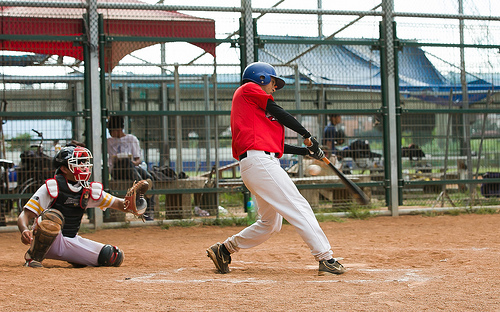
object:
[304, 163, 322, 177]
ball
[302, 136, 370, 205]
bat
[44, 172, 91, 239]
chestguard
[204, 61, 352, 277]
baseball player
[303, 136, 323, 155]
gloves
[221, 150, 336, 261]
white pants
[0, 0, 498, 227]
dugout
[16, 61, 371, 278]
game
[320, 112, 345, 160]
man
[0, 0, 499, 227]
fence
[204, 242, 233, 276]
shoe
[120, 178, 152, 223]
glove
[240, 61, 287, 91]
baseball helmet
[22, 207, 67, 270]
knee pads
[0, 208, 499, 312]
dirt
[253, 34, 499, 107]
canopy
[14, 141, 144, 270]
boy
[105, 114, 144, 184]
fan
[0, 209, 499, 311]
field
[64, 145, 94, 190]
mask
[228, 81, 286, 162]
jersey